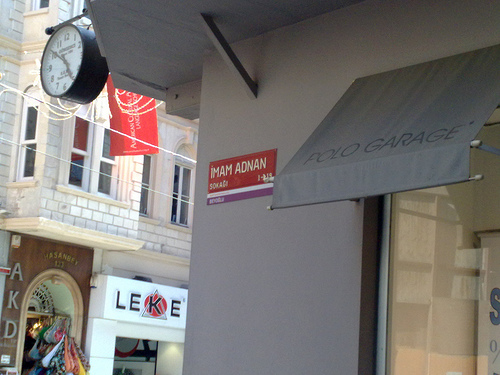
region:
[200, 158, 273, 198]
a sign on the building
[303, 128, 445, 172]
logo on the shade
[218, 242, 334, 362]
the wall is grey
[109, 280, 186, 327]
logo on the white building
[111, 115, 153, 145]
a red banner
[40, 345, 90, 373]
items hanging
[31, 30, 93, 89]
a clock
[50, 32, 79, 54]
numbers on the clock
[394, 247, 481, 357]
a reflection in the window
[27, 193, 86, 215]
white bricks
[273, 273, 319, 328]
wall of building is gray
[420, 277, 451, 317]
glass in wall is reflective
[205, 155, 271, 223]
red sign on wall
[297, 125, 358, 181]
gray awning over window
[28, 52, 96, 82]
black and white clock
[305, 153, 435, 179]
words on gray awning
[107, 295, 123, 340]
white entrance to building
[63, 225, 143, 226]
building of white stone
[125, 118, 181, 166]
red flag on building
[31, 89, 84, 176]
white power lines on street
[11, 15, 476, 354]
This photo is taken at a store front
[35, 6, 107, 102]
This is a clock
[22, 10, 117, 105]
the clock is hanging from a buliding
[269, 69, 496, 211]
This is an canopy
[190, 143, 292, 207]
This sign is red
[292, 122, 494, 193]
This sign says polo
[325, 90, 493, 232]
The canopy is gray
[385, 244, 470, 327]
This is a window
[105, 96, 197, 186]
This flag is red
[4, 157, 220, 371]
This is an urban street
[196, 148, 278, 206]
sign on the wall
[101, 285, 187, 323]
leke logo on the building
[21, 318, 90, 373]
purses hanging on hangers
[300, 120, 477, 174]
polo garage logo on the canopy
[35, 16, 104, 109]
clock on the pole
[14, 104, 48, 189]
window on the building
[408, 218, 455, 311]
glass front of the building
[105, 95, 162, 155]
red flag hanging from building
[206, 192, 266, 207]
purple line on the sign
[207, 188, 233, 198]
white line on the sign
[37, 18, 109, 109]
A rounded street clock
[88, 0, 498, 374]
The gray painted building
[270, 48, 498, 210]
The gray garage awning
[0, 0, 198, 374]
The building block on the left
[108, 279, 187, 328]
The painted shop name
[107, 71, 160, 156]
The hanging red sign board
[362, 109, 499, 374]
A blocked glass door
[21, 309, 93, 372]
The sale merchandise on the window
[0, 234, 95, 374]
The brown painted window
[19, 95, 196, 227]
The glass window on building